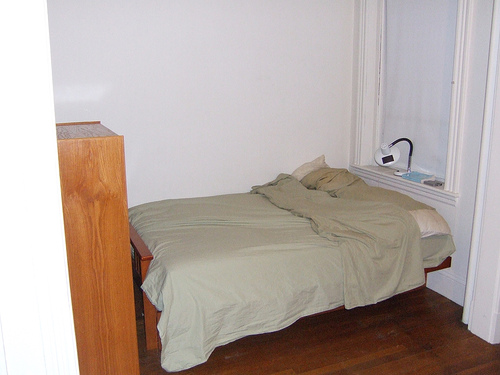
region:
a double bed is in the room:
[129, 157, 454, 319]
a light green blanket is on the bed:
[129, 177, 423, 368]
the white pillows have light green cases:
[295, 151, 449, 248]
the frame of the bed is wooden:
[128, 202, 460, 355]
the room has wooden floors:
[133, 277, 499, 373]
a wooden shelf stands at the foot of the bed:
[56, 116, 145, 373]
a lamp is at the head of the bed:
[372, 136, 414, 182]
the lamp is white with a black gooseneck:
[373, 134, 414, 180]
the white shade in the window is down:
[379, 0, 461, 183]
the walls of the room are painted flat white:
[58, 3, 498, 355]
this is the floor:
[337, 326, 444, 373]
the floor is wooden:
[382, 323, 450, 353]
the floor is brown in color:
[360, 309, 452, 356]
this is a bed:
[138, 152, 458, 367]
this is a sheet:
[209, 204, 275, 254]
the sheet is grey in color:
[226, 198, 297, 273]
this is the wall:
[139, 42, 316, 131]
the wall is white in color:
[194, 37, 348, 140]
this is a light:
[378, 138, 417, 169]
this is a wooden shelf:
[60, 138, 132, 291]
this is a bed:
[163, 195, 405, 299]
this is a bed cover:
[214, 227, 261, 264]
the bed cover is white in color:
[207, 247, 260, 280]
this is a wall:
[172, 23, 296, 142]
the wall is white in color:
[218, 20, 261, 43]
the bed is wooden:
[133, 243, 146, 260]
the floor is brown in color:
[392, 337, 468, 362]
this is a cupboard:
[76, 144, 131, 282]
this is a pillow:
[424, 213, 442, 238]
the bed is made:
[148, 144, 416, 311]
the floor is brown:
[303, 315, 422, 370]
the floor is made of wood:
[316, 313, 428, 366]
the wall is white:
[156, 37, 323, 156]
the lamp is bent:
[357, 114, 437, 201]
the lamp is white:
[342, 132, 399, 172]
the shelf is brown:
[61, 120, 151, 371]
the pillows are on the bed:
[291, 147, 473, 331]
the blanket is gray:
[165, 170, 385, 320]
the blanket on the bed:
[124, 148, 498, 373]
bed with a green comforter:
[127, 147, 474, 369]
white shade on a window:
[382, 1, 454, 146]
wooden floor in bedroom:
[305, 329, 460, 368]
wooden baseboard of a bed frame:
[129, 225, 152, 268]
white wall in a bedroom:
[121, 12, 342, 115]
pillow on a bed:
[406, 206, 452, 238]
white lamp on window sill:
[372, 120, 415, 176]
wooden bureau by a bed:
[58, 112, 147, 373]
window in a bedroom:
[345, 0, 472, 205]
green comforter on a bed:
[163, 210, 295, 258]